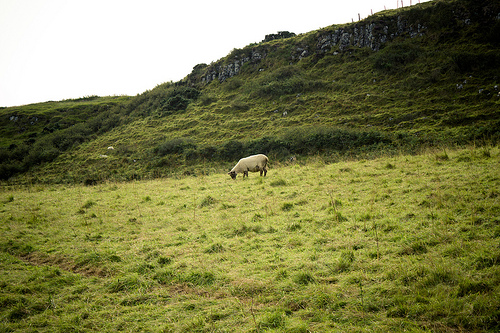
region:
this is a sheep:
[197, 131, 292, 198]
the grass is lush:
[276, 262, 349, 323]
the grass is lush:
[340, 160, 430, 271]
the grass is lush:
[316, 237, 408, 322]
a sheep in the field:
[219, 134, 274, 191]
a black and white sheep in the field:
[218, 137, 279, 181]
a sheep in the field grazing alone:
[212, 138, 282, 190]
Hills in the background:
[273, 50, 400, 122]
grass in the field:
[249, 188, 385, 245]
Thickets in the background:
[285, 124, 355, 149]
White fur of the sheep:
[238, 157, 261, 169]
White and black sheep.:
[226, 152, 271, 178]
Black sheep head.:
[226, 168, 236, 180]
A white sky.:
[2, 2, 393, 104]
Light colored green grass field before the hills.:
[4, 149, 499, 328]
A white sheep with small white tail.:
[227, 154, 271, 179]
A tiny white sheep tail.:
[262, 155, 268, 165]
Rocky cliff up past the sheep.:
[192, 5, 498, 89]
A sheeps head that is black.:
[227, 169, 237, 182]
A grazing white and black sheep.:
[227, 154, 269, 181]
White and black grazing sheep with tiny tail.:
[229, 155, 269, 179]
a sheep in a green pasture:
[104, 25, 418, 317]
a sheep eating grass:
[167, 123, 357, 215]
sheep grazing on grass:
[133, 74, 423, 263]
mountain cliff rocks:
[193, 6, 453, 121]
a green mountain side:
[102, 5, 432, 194]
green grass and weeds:
[60, 154, 449, 314]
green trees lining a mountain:
[25, 64, 210, 155]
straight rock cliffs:
[178, 40, 298, 102]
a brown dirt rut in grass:
[21, 225, 364, 317]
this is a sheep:
[215, 137, 296, 200]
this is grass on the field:
[215, 234, 297, 291]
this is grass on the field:
[320, 223, 398, 308]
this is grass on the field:
[53, 200, 135, 284]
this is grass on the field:
[99, 270, 189, 322]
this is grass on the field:
[175, 176, 240, 243]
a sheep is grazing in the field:
[220, 146, 276, 184]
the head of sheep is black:
[226, 149, 271, 184]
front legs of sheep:
[237, 169, 251, 181]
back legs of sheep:
[256, 166, 269, 176]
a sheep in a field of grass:
[225, 140, 267, 181]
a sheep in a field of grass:
[102, 142, 117, 148]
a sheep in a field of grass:
[90, 147, 108, 157]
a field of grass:
[11, 171, 491, 326]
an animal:
[219, 148, 286, 179]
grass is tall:
[281, 207, 357, 273]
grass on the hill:
[353, 65, 410, 107]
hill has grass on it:
[315, 85, 355, 121]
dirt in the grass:
[72, 255, 120, 290]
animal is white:
[227, 154, 278, 180]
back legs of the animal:
[254, 169, 266, 178]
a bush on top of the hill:
[262, 27, 292, 42]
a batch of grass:
[279, 215, 302, 232]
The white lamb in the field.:
[226, 150, 271, 180]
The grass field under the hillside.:
[1, 144, 498, 330]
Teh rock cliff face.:
[200, 3, 487, 86]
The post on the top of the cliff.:
[358, 12, 362, 21]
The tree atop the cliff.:
[257, 30, 299, 40]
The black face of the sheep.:
[228, 171, 239, 181]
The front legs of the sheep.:
[240, 170, 250, 180]